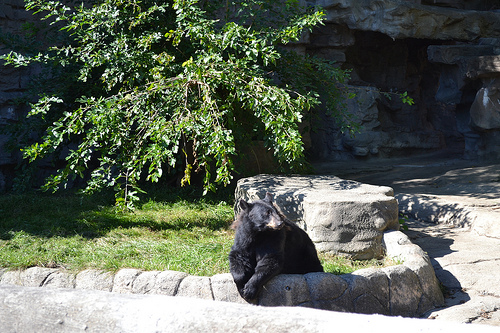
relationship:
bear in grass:
[222, 189, 329, 310] [6, 201, 231, 266]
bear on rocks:
[222, 189, 329, 310] [0, 262, 450, 312]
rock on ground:
[311, 176, 398, 259] [324, 252, 394, 269]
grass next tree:
[6, 201, 231, 266] [0, 2, 333, 197]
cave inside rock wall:
[340, 28, 453, 145] [288, 2, 498, 158]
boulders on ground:
[311, 176, 398, 259] [324, 252, 394, 269]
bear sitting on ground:
[222, 189, 329, 310] [324, 252, 394, 269]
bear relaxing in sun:
[222, 189, 329, 310] [1, 149, 491, 319]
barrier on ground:
[0, 262, 450, 312] [324, 252, 394, 269]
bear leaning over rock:
[222, 189, 329, 310] [0, 262, 450, 312]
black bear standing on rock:
[222, 189, 329, 310] [0, 262, 450, 312]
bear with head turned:
[222, 189, 329, 310] [233, 188, 299, 241]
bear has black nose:
[222, 189, 329, 310] [275, 217, 286, 226]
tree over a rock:
[0, 2, 333, 197] [311, 176, 398, 259]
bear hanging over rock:
[222, 189, 329, 310] [0, 262, 450, 312]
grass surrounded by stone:
[6, 201, 231, 266] [0, 262, 450, 312]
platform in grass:
[233, 169, 401, 210] [6, 201, 231, 266]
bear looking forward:
[222, 189, 329, 310] [233, 188, 299, 241]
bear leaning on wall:
[222, 189, 329, 310] [0, 262, 450, 312]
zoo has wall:
[6, 5, 498, 330] [0, 1, 495, 148]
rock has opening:
[288, 2, 498, 158] [340, 28, 453, 145]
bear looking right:
[222, 189, 329, 310] [472, 5, 494, 326]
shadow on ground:
[84, 193, 218, 254] [6, 201, 231, 266]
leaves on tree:
[0, 3, 327, 216] [0, 2, 333, 197]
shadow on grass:
[0, 174, 238, 240] [6, 201, 231, 266]